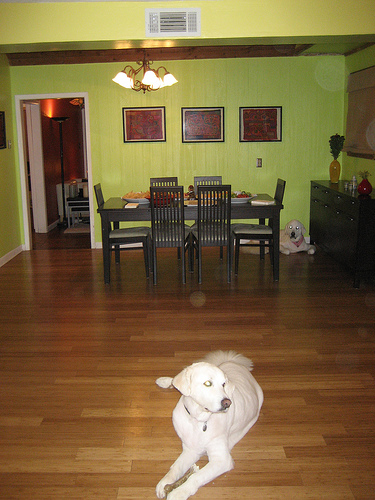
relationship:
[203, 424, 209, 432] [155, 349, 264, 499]
tag on dog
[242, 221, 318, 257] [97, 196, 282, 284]
dog behind table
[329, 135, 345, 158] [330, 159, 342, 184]
plant in vase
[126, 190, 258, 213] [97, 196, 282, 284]
food on table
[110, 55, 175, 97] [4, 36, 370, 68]
light on ceiling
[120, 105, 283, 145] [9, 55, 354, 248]
art on wall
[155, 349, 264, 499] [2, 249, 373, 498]
dog on floor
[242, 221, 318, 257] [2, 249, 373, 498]
dog on floor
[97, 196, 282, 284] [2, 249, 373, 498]
table on floor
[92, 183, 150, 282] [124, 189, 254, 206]
chair for dinner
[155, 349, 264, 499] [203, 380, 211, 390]
dog has eye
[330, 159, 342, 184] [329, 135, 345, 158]
vase with plant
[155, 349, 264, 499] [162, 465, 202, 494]
dog with bone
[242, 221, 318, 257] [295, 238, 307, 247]
dog wearing bandana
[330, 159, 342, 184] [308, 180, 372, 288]
vase on hutch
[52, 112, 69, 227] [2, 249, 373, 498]
lamp on floor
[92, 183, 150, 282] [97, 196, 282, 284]
chair at table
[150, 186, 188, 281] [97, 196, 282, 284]
chair at table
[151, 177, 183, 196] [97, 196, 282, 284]
chair at table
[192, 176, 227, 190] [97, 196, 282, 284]
chair at table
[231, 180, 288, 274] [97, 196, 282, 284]
chair at table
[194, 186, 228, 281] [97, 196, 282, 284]
chair at table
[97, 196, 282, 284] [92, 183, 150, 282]
table has chair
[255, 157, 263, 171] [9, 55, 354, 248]
switch on wall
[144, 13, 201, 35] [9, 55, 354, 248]
vent in wall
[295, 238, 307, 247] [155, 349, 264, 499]
bandana on dog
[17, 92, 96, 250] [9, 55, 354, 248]
door in wall